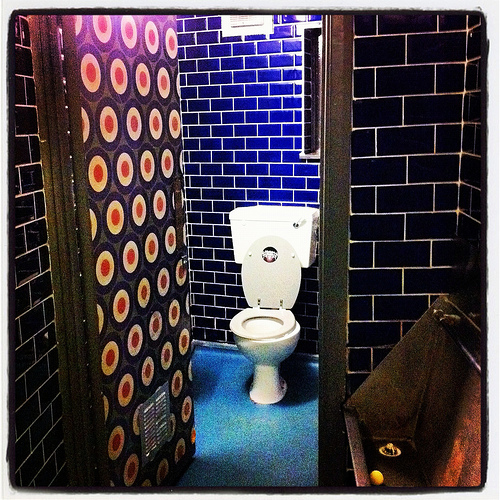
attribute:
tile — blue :
[196, 129, 243, 195]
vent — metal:
[138, 382, 171, 459]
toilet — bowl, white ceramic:
[211, 191, 332, 413]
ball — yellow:
[371, 466, 385, 484]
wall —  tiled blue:
[143, 27, 370, 399]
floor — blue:
[153, 328, 320, 485]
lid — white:
[237, 229, 304, 314]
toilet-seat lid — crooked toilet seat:
[225, 306, 296, 343]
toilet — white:
[222, 202, 323, 409]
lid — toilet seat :
[241, 232, 302, 309]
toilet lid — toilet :
[243, 266, 295, 301]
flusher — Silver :
[288, 214, 309, 231]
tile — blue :
[230, 95, 262, 112]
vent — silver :
[137, 380, 173, 466]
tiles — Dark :
[349, 27, 481, 77]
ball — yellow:
[358, 461, 396, 490]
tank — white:
[227, 204, 318, 268]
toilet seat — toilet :
[239, 236, 301, 308]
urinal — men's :
[224, 205, 321, 405]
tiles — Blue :
[200, 29, 321, 211]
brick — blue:
[218, 55, 245, 68]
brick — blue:
[280, 97, 302, 106]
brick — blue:
[208, 98, 233, 110]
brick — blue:
[218, 139, 248, 151]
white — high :
[219, 15, 276, 39]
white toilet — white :
[225, 205, 318, 406]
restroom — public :
[182, 18, 316, 482]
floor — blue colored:
[194, 342, 316, 476]